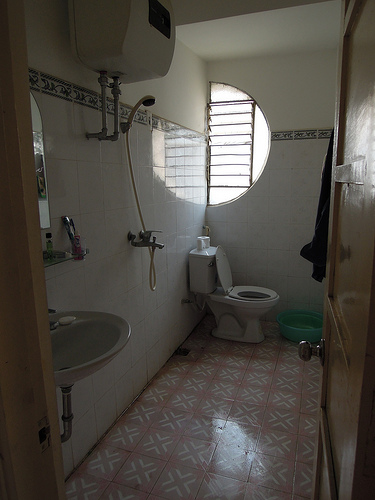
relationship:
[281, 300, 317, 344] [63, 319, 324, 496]
bowl has floor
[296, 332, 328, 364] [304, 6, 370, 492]
door knob on door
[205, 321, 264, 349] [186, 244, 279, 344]
base of toilet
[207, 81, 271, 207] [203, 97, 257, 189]
window with rack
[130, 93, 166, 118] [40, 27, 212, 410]
head attached to wall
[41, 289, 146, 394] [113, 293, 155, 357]
sink oval sink attached to wall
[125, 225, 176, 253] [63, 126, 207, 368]
faucet attached to wall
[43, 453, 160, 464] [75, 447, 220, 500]
pink and white patterened flooring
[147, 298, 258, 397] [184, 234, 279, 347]
standard size white toilet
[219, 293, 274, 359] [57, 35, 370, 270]
base of a toilet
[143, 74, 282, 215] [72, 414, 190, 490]
reflection makes a circle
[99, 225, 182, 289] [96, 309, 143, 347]
shower head on wall